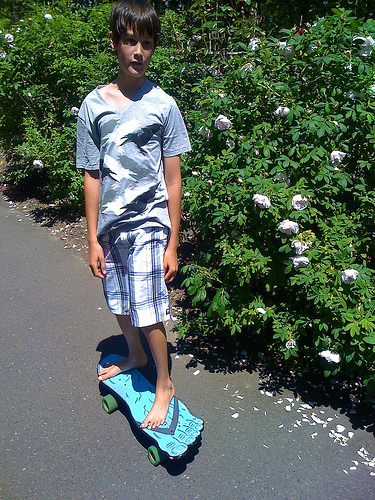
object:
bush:
[181, 25, 373, 376]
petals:
[230, 411, 239, 421]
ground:
[0, 195, 373, 498]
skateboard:
[97, 350, 204, 466]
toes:
[162, 437, 189, 462]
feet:
[142, 381, 174, 432]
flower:
[214, 109, 229, 132]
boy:
[76, 0, 190, 432]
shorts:
[91, 225, 178, 329]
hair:
[104, 0, 167, 36]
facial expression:
[125, 45, 149, 72]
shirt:
[74, 74, 190, 240]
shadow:
[95, 325, 374, 442]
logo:
[164, 308, 173, 317]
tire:
[100, 390, 118, 415]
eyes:
[123, 36, 138, 50]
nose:
[135, 47, 145, 59]